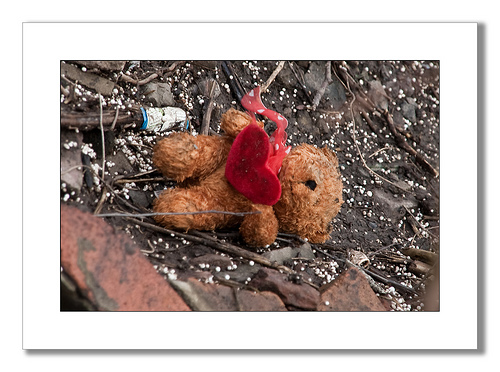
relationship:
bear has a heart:
[153, 106, 344, 247] [222, 125, 280, 205]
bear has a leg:
[153, 106, 344, 247] [152, 130, 213, 182]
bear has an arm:
[153, 106, 344, 247] [220, 108, 255, 136]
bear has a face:
[153, 106, 344, 247] [279, 149, 339, 220]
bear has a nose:
[153, 106, 344, 247] [307, 176, 318, 188]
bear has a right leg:
[153, 106, 344, 247] [158, 186, 215, 232]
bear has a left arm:
[153, 106, 344, 247] [237, 210, 278, 247]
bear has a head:
[153, 106, 344, 247] [280, 142, 344, 241]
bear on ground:
[153, 106, 344, 247] [61, 60, 441, 311]